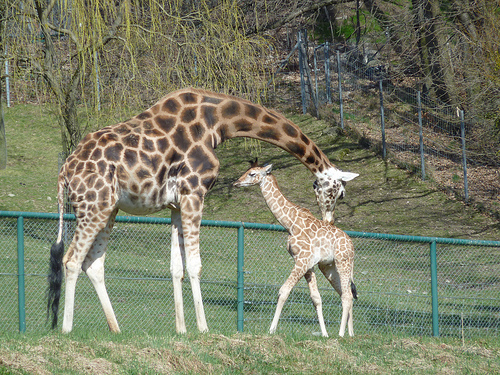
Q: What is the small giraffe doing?
A: It's standing.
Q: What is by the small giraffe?
A: A big giraffe.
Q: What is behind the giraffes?
A: A fence.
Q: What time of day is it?
A: It's daytime.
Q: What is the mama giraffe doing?
A: Sniffing her baby.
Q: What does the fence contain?
A: It's giraffes.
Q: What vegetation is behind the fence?
A: The trees.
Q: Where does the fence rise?
A: Up the hillside.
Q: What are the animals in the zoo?
A: The giraffe.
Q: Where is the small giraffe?
A: Near the mother.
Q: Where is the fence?
A: Behind the giraffes.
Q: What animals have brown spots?
A: Giraffes.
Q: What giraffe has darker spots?
A: The mother giraffe.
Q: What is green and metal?
A: The fence.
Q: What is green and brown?
A: The grass.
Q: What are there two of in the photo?
A: GIraffes.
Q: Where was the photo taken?
A: At a zoo.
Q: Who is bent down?
A: Mother giraffe.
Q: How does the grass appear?
A: Green and lush.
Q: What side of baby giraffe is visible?
A: Left side.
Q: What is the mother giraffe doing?
A: Grooming baby.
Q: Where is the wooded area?
A: Behind fence.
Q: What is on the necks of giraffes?
A: Names.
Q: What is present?
A: Animals.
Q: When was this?
A: Daytime.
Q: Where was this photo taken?
A: A zoo.